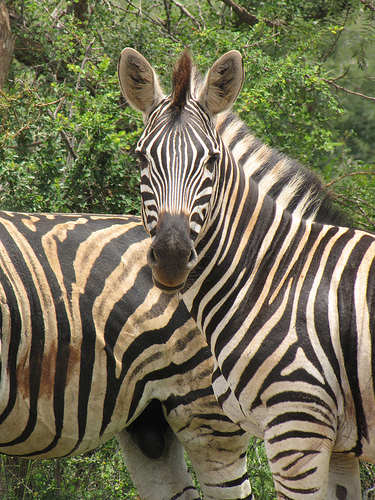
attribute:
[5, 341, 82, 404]
spot — mud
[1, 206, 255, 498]
zebra — white, black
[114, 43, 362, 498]
zebra — black, white, brown, striped, looking ahead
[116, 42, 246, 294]
head — zebra's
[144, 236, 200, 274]
nose — zebra's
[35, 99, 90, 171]
leaves — green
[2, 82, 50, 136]
leaves — green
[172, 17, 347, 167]
tree — brown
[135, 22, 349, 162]
tree — brown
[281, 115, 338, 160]
leaves — green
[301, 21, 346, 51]
leaves — green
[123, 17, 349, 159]
tree — brown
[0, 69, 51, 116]
leaves — green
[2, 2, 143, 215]
tree — brown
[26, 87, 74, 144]
leaves — green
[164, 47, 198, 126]
mane — mohawk shaped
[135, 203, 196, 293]
nose — black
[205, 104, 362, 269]
mane — black, white, striped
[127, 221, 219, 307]
nose — black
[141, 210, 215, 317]
nose — black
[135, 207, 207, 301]
nose — black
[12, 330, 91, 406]
stain — brown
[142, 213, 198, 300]
muzzle — black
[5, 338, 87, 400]
spot — brown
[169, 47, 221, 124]
mohawk — red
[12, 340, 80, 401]
patch — brown